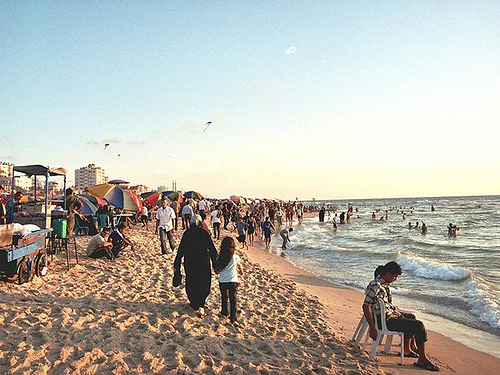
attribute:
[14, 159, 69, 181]
canopy — over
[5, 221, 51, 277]
wagon — blue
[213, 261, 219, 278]
girl's hand — holding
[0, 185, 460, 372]
people gathering — large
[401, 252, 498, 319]
waves — large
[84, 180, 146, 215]
umbrella — colored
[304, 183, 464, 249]
people — swimming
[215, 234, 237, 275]
hair — long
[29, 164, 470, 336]
people — pictured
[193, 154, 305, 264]
some people — sitting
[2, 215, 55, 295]
wagon — wooden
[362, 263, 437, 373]
person — sitting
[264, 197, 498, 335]
tide — coming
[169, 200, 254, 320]
people — pictured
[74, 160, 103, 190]
building — white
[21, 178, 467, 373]
people — pictured